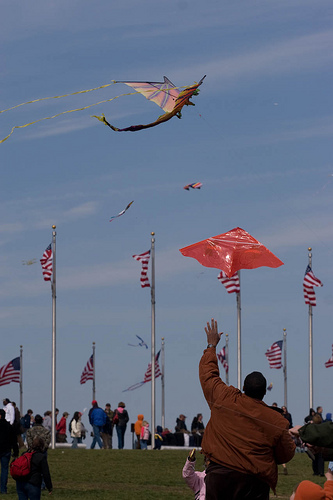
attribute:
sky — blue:
[0, 2, 332, 454]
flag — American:
[35, 238, 52, 290]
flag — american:
[132, 236, 155, 286]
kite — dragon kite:
[184, 173, 208, 205]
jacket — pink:
[182, 463, 207, 491]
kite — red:
[180, 222, 289, 281]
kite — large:
[0, 72, 209, 142]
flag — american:
[133, 248, 152, 287]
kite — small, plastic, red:
[179, 226, 284, 278]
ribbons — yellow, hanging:
[3, 68, 133, 136]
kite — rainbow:
[183, 177, 202, 189]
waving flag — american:
[75, 213, 211, 325]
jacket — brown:
[186, 347, 302, 483]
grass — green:
[80, 449, 152, 475]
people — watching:
[5, 312, 331, 491]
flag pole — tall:
[43, 223, 59, 450]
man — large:
[198, 317, 297, 498]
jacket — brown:
[198, 344, 295, 490]